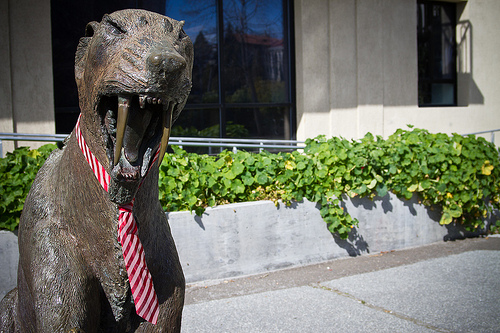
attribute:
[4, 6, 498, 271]
scene — outdoors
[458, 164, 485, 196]
leaves — green 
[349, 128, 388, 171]
leaves — green 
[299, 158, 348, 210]
leaves — green 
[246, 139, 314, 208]
leaves — green 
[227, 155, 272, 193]
leaves — green 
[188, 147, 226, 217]
leaves — green 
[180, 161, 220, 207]
leaves — green 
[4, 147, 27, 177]
leaves — green 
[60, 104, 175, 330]
tie — red, white , striped 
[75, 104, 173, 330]
tie — striped , red, white 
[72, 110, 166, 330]
tie — white , red, striped 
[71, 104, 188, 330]
tie — striped , red, white 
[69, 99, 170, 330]
tie — striped , red, white 